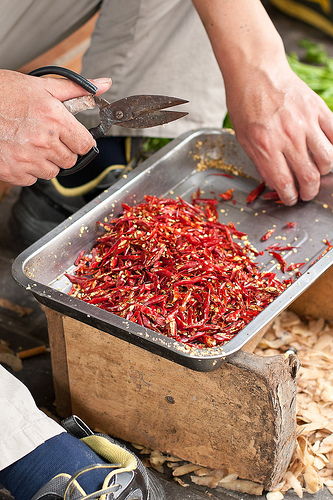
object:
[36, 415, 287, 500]
shoe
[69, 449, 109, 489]
foot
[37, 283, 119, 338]
edge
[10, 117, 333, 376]
tin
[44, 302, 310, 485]
block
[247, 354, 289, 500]
wood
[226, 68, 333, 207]
hand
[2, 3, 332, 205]
man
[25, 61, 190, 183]
shears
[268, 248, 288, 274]
peppers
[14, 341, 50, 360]
cigarette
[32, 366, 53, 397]
ground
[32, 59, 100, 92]
handle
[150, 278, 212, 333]
pile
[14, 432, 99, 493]
sock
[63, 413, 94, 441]
tag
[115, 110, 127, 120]
screw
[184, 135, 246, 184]
corner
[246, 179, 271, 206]
pepper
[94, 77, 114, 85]
nail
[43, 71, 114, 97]
thumb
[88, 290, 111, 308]
chilis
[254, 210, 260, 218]
seeds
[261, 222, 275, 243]
chili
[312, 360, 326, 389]
shavings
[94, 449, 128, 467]
interior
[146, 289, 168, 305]
chilies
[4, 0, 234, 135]
pants